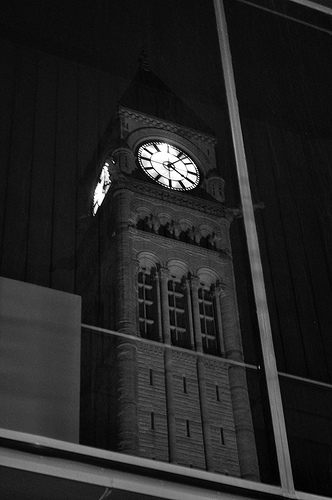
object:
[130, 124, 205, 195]
clock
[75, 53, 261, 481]
tower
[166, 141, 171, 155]
number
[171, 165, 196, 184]
hand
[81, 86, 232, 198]
roof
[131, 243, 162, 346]
window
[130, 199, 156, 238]
arch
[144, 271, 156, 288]
pane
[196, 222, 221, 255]
opening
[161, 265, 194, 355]
window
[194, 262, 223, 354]
window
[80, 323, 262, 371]
bar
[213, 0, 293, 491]
pole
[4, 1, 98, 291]
wall